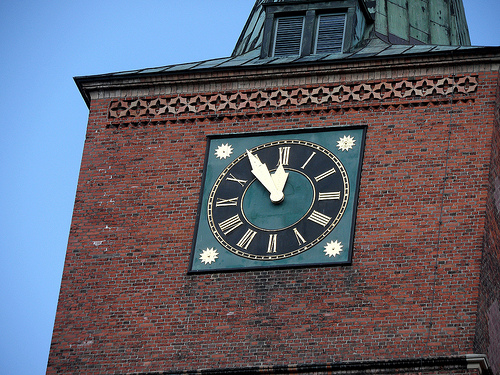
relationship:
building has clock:
[43, 0, 499, 375] [203, 140, 353, 268]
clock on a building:
[203, 140, 353, 268] [43, 0, 499, 375]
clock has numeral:
[203, 140, 353, 268] [276, 142, 291, 170]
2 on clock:
[276, 142, 291, 170] [203, 140, 353, 268]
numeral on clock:
[316, 192, 342, 203] [203, 140, 353, 268]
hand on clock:
[240, 151, 273, 187] [203, 140, 353, 268]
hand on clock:
[274, 165, 288, 185] [203, 140, 353, 268]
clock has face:
[203, 140, 353, 268] [215, 147, 337, 254]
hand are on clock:
[243, 149, 280, 201] [203, 140, 353, 268]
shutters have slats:
[270, 8, 347, 53] [281, 17, 343, 45]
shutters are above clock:
[270, 8, 347, 53] [203, 140, 353, 268]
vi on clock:
[262, 231, 283, 251] [203, 140, 353, 268]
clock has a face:
[203, 140, 353, 268] [215, 147, 337, 254]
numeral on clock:
[277, 146, 291, 166] [203, 140, 353, 268]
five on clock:
[289, 231, 306, 245] [203, 140, 353, 268]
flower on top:
[214, 145, 234, 159] [205, 135, 363, 148]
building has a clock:
[43, 0, 499, 375] [203, 140, 353, 268]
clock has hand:
[203, 140, 353, 268] [243, 149, 280, 201]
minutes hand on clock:
[240, 151, 273, 187] [203, 140, 353, 268]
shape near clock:
[338, 138, 356, 151] [203, 140, 353, 268]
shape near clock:
[318, 243, 352, 259] [203, 140, 353, 268]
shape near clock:
[199, 250, 217, 263] [203, 140, 353, 268]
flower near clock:
[213, 142, 234, 159] [203, 140, 353, 268]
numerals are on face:
[214, 147, 340, 260] [215, 147, 337, 254]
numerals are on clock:
[214, 147, 340, 260] [203, 140, 353, 268]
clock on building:
[203, 140, 353, 268] [56, 87, 495, 359]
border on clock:
[178, 126, 388, 277] [203, 140, 353, 268]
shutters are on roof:
[270, 16, 349, 56] [83, 45, 500, 76]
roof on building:
[83, 45, 500, 76] [56, 87, 495, 359]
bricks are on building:
[395, 159, 489, 324] [56, 87, 495, 359]